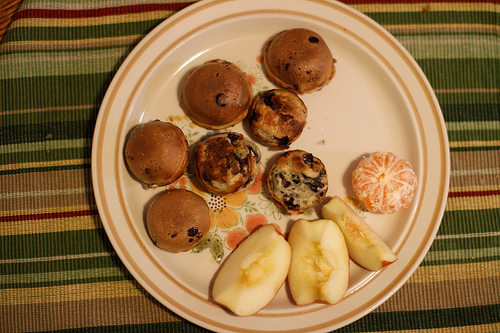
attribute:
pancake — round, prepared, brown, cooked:
[264, 28, 338, 95]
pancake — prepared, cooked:
[180, 59, 253, 131]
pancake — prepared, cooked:
[248, 88, 308, 150]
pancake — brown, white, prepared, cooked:
[193, 132, 261, 195]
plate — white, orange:
[90, 0, 450, 332]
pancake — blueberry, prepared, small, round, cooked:
[267, 149, 328, 215]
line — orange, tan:
[114, 9, 428, 318]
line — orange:
[97, 0, 447, 332]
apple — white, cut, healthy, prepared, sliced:
[211, 224, 292, 316]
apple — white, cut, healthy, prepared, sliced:
[287, 218, 350, 305]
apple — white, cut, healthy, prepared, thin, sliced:
[320, 195, 398, 272]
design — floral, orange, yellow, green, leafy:
[165, 54, 368, 265]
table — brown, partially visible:
[0, 0, 22, 44]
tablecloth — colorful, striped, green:
[1, 0, 500, 333]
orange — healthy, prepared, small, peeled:
[351, 151, 418, 214]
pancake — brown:
[147, 189, 211, 254]